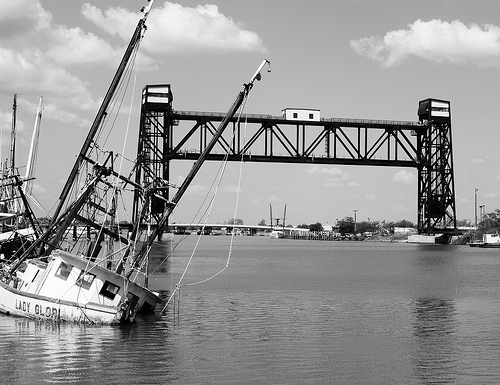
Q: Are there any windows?
A: Yes, there are windows.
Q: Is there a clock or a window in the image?
A: Yes, there are windows.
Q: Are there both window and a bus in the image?
A: No, there are windows but no buses.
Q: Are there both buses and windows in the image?
A: No, there are windows but no buses.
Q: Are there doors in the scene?
A: No, there are no doors.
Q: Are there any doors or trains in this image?
A: No, there are no doors or trains.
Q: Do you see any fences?
A: No, there are no fences.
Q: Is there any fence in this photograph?
A: No, there are no fences.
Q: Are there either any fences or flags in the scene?
A: No, there are no fences or flags.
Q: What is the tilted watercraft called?
A: The watercraft is a ship.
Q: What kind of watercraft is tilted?
A: The watercraft is a ship.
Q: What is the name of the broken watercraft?
A: The watercraft is a ship.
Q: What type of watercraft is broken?
A: The watercraft is a ship.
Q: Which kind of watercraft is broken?
A: The watercraft is a ship.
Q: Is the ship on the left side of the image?
A: Yes, the ship is on the left of the image.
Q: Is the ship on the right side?
A: No, the ship is on the left of the image.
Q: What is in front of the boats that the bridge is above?
A: The ship is in front of the boats.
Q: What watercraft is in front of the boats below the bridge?
A: The watercraft is a ship.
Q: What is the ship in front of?
A: The ship is in front of the boats.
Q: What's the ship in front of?
A: The ship is in front of the boats.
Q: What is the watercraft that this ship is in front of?
A: The watercraft is boats.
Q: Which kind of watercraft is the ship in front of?
A: The ship is in front of the boats.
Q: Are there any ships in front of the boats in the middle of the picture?
A: Yes, there is a ship in front of the boats.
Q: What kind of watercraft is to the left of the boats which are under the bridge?
A: The watercraft is a ship.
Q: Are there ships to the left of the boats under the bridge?
A: Yes, there is a ship to the left of the boats.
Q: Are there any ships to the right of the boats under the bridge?
A: No, the ship is to the left of the boats.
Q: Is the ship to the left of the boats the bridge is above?
A: Yes, the ship is to the left of the boats.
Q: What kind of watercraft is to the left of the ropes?
A: The watercraft is a ship.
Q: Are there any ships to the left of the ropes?
A: Yes, there is a ship to the left of the ropes.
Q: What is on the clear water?
A: The ship is on the water.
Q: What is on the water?
A: The ship is on the water.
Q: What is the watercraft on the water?
A: The watercraft is a ship.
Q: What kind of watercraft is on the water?
A: The watercraft is a ship.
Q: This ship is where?
A: The ship is on the water.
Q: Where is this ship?
A: The ship is on the water.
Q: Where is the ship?
A: The ship is on the water.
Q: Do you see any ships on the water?
A: Yes, there is a ship on the water.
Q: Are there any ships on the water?
A: Yes, there is a ship on the water.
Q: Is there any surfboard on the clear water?
A: No, there is a ship on the water.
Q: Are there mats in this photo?
A: No, there are no mats.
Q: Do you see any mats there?
A: No, there are no mats.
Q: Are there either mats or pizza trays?
A: No, there are no mats or pizza trays.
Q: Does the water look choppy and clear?
A: No, the water is clear but calm.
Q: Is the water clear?
A: Yes, the water is clear.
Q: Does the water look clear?
A: Yes, the water is clear.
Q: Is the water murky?
A: No, the water is clear.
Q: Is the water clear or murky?
A: The water is clear.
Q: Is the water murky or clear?
A: The water is clear.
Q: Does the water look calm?
A: Yes, the water is calm.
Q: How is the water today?
A: The water is calm.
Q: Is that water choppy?
A: No, the water is calm.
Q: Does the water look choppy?
A: No, the water is calm.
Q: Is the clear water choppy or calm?
A: The water is calm.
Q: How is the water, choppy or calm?
A: The water is calm.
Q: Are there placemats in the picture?
A: No, there are no placemats.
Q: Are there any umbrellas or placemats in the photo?
A: No, there are no placemats or umbrellas.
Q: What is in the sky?
A: The clouds are in the sky.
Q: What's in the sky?
A: The clouds are in the sky.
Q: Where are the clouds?
A: The clouds are in the sky.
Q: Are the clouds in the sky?
A: Yes, the clouds are in the sky.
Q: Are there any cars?
A: No, there are no cars.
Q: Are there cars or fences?
A: No, there are no cars or fences.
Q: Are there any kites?
A: No, there are no kites.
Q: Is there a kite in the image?
A: No, there are no kites.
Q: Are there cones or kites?
A: No, there are no kites or cones.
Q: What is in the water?
A: The ropes are in the water.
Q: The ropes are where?
A: The ropes are in the water.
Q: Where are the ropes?
A: The ropes are in the water.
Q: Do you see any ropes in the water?
A: Yes, there are ropes in the water.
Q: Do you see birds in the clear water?
A: No, there are ropes in the water.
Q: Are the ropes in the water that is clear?
A: Yes, the ropes are in the water.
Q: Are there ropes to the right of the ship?
A: Yes, there are ropes to the right of the ship.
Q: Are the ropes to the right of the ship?
A: Yes, the ropes are to the right of the ship.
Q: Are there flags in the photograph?
A: No, there are no flags.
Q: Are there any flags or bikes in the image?
A: No, there are no flags or bikes.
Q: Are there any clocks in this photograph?
A: No, there are no clocks.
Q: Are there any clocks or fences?
A: No, there are no clocks or fences.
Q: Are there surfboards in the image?
A: No, there are no surfboards.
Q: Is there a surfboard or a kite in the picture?
A: No, there are no surfboards or kites.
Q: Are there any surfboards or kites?
A: No, there are no surfboards or kites.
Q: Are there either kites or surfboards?
A: No, there are no surfboards or kites.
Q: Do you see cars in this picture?
A: No, there are no cars.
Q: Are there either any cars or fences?
A: No, there are no cars or fences.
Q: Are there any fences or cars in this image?
A: No, there are no cars or fences.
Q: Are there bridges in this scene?
A: Yes, there is a bridge.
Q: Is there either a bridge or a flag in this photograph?
A: Yes, there is a bridge.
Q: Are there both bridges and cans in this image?
A: No, there is a bridge but no cans.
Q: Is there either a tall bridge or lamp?
A: Yes, there is a tall bridge.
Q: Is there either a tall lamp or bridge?
A: Yes, there is a tall bridge.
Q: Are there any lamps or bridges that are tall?
A: Yes, the bridge is tall.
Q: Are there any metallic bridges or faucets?
A: Yes, there is a metal bridge.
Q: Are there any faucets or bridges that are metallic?
A: Yes, the bridge is metallic.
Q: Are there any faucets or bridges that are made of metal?
A: Yes, the bridge is made of metal.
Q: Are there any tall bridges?
A: Yes, there is a tall bridge.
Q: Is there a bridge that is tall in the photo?
A: Yes, there is a tall bridge.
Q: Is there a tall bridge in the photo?
A: Yes, there is a tall bridge.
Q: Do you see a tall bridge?
A: Yes, there is a tall bridge.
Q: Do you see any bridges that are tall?
A: Yes, there is a bridge that is tall.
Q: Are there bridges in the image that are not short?
A: Yes, there is a tall bridge.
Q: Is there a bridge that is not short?
A: Yes, there is a tall bridge.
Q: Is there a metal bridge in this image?
A: Yes, there is a metal bridge.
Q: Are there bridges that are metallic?
A: Yes, there is a bridge that is metallic.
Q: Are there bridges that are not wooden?
A: Yes, there is a metallic bridge.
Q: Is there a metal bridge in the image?
A: Yes, there is a bridge that is made of metal.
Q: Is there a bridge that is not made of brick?
A: Yes, there is a bridge that is made of metal.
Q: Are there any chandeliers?
A: No, there are no chandeliers.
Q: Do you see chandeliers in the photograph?
A: No, there are no chandeliers.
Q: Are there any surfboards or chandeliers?
A: No, there are no chandeliers or surfboards.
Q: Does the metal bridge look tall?
A: Yes, the bridge is tall.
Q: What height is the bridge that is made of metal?
A: The bridge is tall.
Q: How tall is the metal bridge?
A: The bridge is tall.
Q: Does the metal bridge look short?
A: No, the bridge is tall.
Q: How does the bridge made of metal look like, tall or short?
A: The bridge is tall.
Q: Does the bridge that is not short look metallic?
A: Yes, the bridge is metallic.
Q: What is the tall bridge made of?
A: The bridge is made of metal.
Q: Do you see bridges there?
A: Yes, there is a bridge.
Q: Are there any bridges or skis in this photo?
A: Yes, there is a bridge.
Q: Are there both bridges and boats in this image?
A: Yes, there are both a bridge and a boat.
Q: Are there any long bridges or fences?
A: Yes, there is a long bridge.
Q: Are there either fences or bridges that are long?
A: Yes, the bridge is long.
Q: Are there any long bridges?
A: Yes, there is a long bridge.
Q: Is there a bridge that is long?
A: Yes, there is a bridge that is long.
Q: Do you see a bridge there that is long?
A: Yes, there is a bridge that is long.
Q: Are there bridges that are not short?
A: Yes, there is a long bridge.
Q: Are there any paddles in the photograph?
A: No, there are no paddles.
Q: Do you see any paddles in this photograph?
A: No, there are no paddles.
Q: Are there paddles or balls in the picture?
A: No, there are no paddles or balls.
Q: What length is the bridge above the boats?
A: The bridge is long.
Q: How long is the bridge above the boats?
A: The bridge is long.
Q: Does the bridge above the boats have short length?
A: No, the bridge is long.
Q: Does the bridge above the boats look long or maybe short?
A: The bridge is long.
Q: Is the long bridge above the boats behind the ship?
A: Yes, the bridge is above the boats.